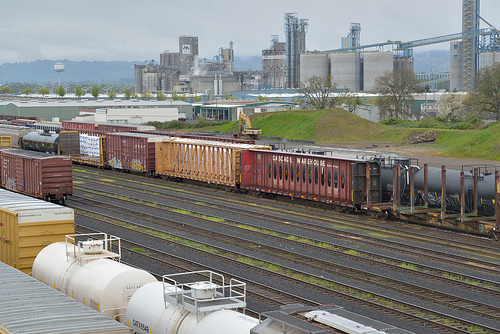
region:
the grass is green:
[251, 106, 323, 136]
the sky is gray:
[73, 12, 156, 54]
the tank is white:
[36, 239, 138, 330]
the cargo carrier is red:
[232, 138, 403, 236]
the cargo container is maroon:
[6, 145, 83, 203]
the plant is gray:
[264, 17, 430, 113]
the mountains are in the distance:
[24, 52, 224, 98]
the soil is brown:
[359, 135, 449, 173]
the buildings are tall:
[125, 15, 397, 170]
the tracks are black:
[136, 168, 381, 331]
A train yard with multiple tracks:
[10, 107, 492, 328]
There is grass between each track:
[135, 187, 351, 322]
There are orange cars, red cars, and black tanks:
[14, 105, 488, 243]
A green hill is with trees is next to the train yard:
[206, 81, 497, 184]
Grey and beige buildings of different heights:
[128, 7, 495, 94]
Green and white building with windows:
[182, 91, 293, 125]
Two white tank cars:
[22, 209, 227, 332]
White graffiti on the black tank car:
[417, 180, 455, 215]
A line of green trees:
[5, 82, 277, 99]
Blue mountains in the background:
[7, 50, 171, 96]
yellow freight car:
[144, 134, 253, 189]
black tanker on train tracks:
[407, 160, 498, 225]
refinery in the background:
[128, 15, 498, 99]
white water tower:
[46, 59, 71, 91]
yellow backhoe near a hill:
[217, 107, 272, 145]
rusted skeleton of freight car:
[363, 162, 495, 239]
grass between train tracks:
[92, 166, 305, 300]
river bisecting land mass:
[19, 90, 286, 127]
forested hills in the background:
[11, 54, 246, 91]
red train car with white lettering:
[238, 144, 385, 223]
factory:
[116, 8, 473, 110]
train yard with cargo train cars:
[18, 81, 481, 318]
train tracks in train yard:
[117, 178, 447, 310]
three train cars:
[107, 131, 384, 238]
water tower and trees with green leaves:
[45, 51, 88, 108]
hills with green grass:
[231, 101, 412, 148]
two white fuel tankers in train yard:
[26, 223, 263, 331]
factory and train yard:
[50, 24, 475, 279]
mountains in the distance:
[8, 31, 142, 101]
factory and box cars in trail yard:
[18, 38, 463, 323]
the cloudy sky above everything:
[2, 2, 499, 54]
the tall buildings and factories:
[121, 32, 496, 90]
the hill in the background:
[1, 58, 137, 86]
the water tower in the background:
[46, 59, 72, 85]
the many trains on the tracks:
[2, 115, 494, 331]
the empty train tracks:
[84, 170, 499, 330]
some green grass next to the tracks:
[262, 101, 497, 171]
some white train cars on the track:
[28, 240, 248, 332]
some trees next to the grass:
[303, 80, 498, 119]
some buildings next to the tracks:
[3, 90, 240, 127]